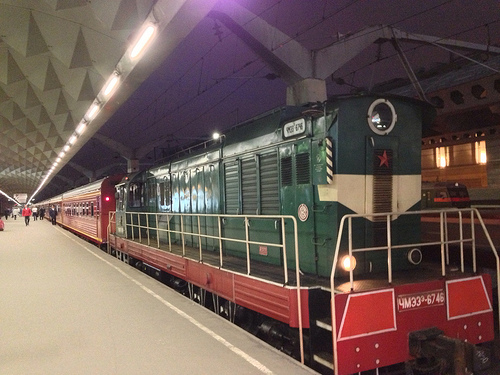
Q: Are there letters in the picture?
A: Yes, there are letters.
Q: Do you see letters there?
A: Yes, there are letters.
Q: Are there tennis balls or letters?
A: Yes, there are letters.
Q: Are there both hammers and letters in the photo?
A: No, there are letters but no hammers.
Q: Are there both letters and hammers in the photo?
A: No, there are letters but no hammers.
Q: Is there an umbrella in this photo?
A: No, there are no umbrellas.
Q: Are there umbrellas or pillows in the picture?
A: No, there are no umbrellas or pillows.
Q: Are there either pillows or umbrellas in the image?
A: No, there are no umbrellas or pillows.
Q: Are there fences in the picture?
A: No, there are no fences.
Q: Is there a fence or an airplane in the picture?
A: No, there are no fences or airplanes.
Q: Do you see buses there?
A: No, there are no buses.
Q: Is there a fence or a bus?
A: No, there are no buses or fences.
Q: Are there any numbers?
A: Yes, there are numbers.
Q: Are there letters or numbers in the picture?
A: Yes, there are numbers.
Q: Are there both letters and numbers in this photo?
A: Yes, there are both numbers and letters.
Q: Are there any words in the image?
A: No, there are no words.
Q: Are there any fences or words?
A: No, there are no words or fences.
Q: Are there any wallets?
A: No, there are no wallets.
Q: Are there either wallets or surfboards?
A: No, there are no wallets or surfboards.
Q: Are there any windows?
A: Yes, there are windows.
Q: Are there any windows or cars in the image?
A: Yes, there are windows.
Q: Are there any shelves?
A: No, there are no shelves.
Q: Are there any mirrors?
A: No, there are no mirrors.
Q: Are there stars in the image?
A: Yes, there is a star.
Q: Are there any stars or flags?
A: Yes, there is a star.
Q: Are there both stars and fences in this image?
A: No, there is a star but no fences.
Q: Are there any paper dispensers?
A: No, there are no paper dispensers.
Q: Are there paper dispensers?
A: No, there are no paper dispensers.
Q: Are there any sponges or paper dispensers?
A: No, there are no paper dispensers or sponges.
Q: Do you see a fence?
A: No, there are no fences.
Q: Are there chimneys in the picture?
A: No, there are no chimneys.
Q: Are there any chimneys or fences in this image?
A: No, there are no chimneys or fences.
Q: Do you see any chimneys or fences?
A: No, there are no chimneys or fences.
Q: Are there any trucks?
A: No, there are no trucks.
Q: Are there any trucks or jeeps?
A: No, there are no trucks or jeeps.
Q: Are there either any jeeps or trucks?
A: No, there are no trucks or jeeps.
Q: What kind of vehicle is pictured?
A: The vehicle is a car.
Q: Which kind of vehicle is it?
A: The vehicle is a car.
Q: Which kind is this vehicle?
A: This is a car.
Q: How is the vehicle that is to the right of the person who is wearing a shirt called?
A: The vehicle is a car.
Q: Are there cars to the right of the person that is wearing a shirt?
A: Yes, there is a car to the right of the person.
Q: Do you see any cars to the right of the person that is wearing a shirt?
A: Yes, there is a car to the right of the person.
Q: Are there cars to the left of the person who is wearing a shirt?
A: No, the car is to the right of the person.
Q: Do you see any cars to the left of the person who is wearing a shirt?
A: No, the car is to the right of the person.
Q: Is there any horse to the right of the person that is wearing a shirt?
A: No, there is a car to the right of the person.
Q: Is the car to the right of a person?
A: Yes, the car is to the right of a person.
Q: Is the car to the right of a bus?
A: No, the car is to the right of a person.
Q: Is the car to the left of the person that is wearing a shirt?
A: No, the car is to the right of the person.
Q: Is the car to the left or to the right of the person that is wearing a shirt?
A: The car is to the right of the person.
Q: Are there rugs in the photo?
A: No, there are no rugs.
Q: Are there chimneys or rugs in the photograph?
A: No, there are no rugs or chimneys.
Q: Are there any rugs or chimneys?
A: No, there are no rugs or chimneys.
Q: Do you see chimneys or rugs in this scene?
A: No, there are no rugs or chimneys.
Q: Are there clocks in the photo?
A: No, there are no clocks.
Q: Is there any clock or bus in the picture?
A: No, there are no clocks or buses.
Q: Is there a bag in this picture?
A: No, there are no bags.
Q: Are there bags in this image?
A: No, there are no bags.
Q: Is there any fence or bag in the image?
A: No, there are no bags or fences.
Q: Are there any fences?
A: No, there are no fences.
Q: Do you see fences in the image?
A: No, there are no fences.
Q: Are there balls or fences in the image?
A: No, there are no fences or balls.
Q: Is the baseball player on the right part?
A: Yes, the player is on the right of the image.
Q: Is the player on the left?
A: No, the player is on the right of the image.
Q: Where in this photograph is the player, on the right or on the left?
A: The player is on the right of the image.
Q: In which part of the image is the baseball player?
A: The player is on the right of the image.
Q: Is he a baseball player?
A: Yes, that is a baseball player.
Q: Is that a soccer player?
A: No, that is a baseball player.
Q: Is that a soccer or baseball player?
A: That is a baseball player.